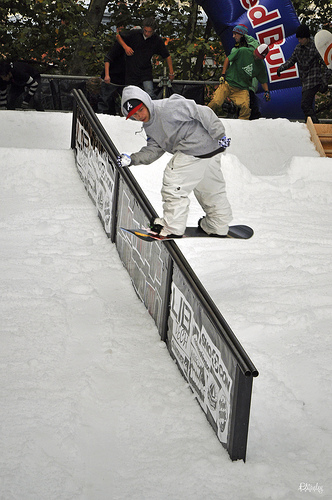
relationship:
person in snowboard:
[117, 17, 173, 117] [314, 28, 331, 69]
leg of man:
[198, 152, 232, 234] [116, 84, 233, 238]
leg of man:
[210, 82, 226, 112] [116, 84, 233, 238]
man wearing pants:
[116, 84, 233, 238] [154, 149, 232, 235]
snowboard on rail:
[118, 225, 253, 243] [36, 71, 227, 88]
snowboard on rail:
[118, 225, 253, 243] [68, 88, 260, 397]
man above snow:
[116, 84, 233, 238] [2, 111, 329, 497]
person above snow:
[204, 43, 272, 120] [2, 111, 329, 497]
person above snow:
[275, 23, 330, 121] [2, 111, 329, 497]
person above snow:
[115, 18, 174, 97] [2, 111, 329, 497]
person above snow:
[229, 21, 258, 46] [2, 111, 329, 497]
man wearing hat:
[116, 84, 233, 238] [117, 102, 136, 114]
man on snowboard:
[109, 78, 235, 237] [114, 222, 255, 255]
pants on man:
[159, 154, 232, 239] [94, 76, 234, 238]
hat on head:
[125, 98, 139, 110] [105, 85, 162, 130]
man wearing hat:
[116, 84, 233, 238] [122, 98, 146, 120]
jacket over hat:
[120, 85, 226, 167] [127, 94, 144, 115]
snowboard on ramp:
[118, 216, 260, 246] [71, 87, 256, 463]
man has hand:
[116, 84, 233, 238] [112, 154, 138, 169]